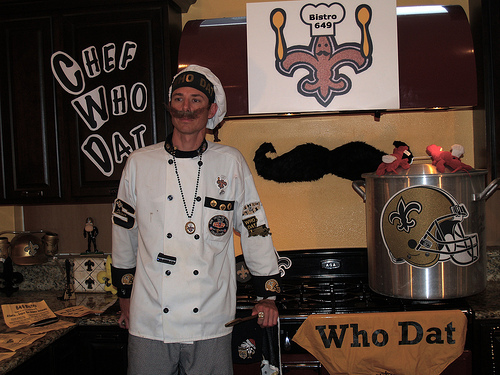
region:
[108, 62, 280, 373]
a man dressed up like a chef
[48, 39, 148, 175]
writing on the cupboard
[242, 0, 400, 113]
a sign with the new orleans saints logo on it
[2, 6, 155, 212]
cupboards next to the oven hood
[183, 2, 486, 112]
the oven hood by the stove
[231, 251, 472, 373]
the black oven in the kitchen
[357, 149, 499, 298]
a very large pot on top of the stove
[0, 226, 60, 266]
a hat with beer cans on it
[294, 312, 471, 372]
a towel hanging on the stove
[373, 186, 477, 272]
a sticker of the new orleans saints helmet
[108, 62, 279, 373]
man wearing a fake mustache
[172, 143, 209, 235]
man wearing necklace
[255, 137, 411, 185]
image of a mustache above stove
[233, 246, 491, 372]
man leaning on a black stove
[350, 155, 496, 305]
large metal stockpot on stove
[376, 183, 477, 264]
football helmet on stockpot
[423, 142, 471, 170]
plush red crawdad in stockpot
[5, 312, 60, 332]
knife with black handle on counter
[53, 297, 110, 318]
piece of paper on counter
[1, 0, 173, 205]
black cabinets behind man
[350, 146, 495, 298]
a huge pot for gumbo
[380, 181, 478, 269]
New Orleans Saints football helmet on the pot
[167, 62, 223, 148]
a chef with a handlebar mustach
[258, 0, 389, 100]
a restaurant's logo with a fleur de lis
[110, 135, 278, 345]
the man has an emblazoned chef's coat on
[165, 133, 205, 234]
the man has a long chain around his neck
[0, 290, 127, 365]
papers are on the countertop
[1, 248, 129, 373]
the counter is a brown marble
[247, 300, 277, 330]
a ring is on the pointer finger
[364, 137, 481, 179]
stuffed animals are on the lid of the pot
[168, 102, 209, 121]
FAKE BLACK MUSTASCH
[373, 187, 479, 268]
FOOTBALL TEAM LOGO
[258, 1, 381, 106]
BISTRO 649 SIGN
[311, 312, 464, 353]
ORANGE AND BLACK TOWEL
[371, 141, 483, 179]
COOK POT LID WITH STUFFED LOBSTERS ON TOP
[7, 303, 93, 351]
PAPER ADVERTISEMENTS.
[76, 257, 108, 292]
BLACK SPADE DESIGN ON KITCHEN DECOR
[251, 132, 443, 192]
BLACK MUSTACHE ON WALL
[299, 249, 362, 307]
CONTROL PANEL ON BACK OF STOVE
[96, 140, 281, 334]
CHEF JACKET WITH DECORATIONS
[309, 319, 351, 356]
the black letter W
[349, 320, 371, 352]
the black letter H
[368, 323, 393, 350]
the black letter O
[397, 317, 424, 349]
the black letter D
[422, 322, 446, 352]
the black letter A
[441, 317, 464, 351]
the black letter T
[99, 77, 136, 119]
a black capitalized H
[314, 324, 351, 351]
a black capitalized W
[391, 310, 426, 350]
the black capitalized D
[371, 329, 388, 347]
the black lowercase O